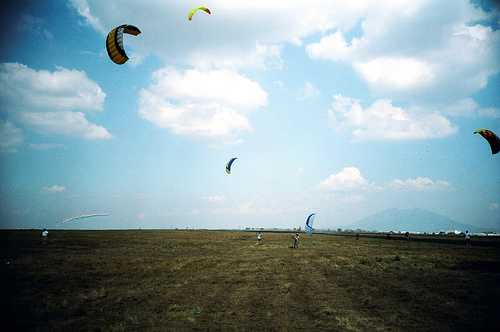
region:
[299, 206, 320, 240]
kite flying in the sky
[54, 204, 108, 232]
kite flying in the sky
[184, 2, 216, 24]
kite flying in the sky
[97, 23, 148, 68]
kite flying in the sky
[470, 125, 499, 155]
kite flying in the sky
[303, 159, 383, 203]
fluffy white cloud in the sky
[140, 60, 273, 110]
fluffy white cloud in the sky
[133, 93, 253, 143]
fluffy white cloud in the sky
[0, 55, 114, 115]
fluffy white cloud in the sky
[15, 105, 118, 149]
fluffy white cloud in the sky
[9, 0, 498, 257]
a bunch of kites flying in the sky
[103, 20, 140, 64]
a yellow, white and blue kite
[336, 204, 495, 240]
a grey colored mountain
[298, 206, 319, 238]
a white and blue kite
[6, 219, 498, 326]
a large open field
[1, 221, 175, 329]
the dark edges of a photograph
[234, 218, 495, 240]
a tree line behind the field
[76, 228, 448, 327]
brown and green grass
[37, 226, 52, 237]
a tiny person wearing a white shirt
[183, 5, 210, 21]
a kite that has yellow, green, and red colors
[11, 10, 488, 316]
People are flying some colorful kites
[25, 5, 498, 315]
People are out in a big field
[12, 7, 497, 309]
People are getting some recreation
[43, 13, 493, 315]
People are having some fun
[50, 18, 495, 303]
People are out in the sunshine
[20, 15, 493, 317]
People are away from the big city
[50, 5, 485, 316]
People are enjoying their time off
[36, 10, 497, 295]
People are enjoying each other's company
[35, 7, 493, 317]
People are testing their kites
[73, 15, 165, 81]
A kite is in the air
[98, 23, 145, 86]
a parachute in the sky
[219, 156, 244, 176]
a blue and yellow parachute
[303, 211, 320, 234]
a blue parachute landing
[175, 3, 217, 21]
a rainbow colored parachute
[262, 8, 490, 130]
clouds in the sky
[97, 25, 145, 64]
white yellow and blue parachute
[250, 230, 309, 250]
people standing in a field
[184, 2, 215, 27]
person parachuting in the clear blue sky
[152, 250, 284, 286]
brown and green grass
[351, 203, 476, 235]
mountains in the distance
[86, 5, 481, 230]
several wind sails in the sky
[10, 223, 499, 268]
several people flying kites in a field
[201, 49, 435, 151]
cloudy blue skies over the field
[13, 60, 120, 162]
fluffy white clouds in the sky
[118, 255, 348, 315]
green grass of the field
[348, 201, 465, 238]
a mountain in the distance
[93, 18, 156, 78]
a yellow white and black wind sail in the sky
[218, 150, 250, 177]
a blue and yellow wind sail in the sky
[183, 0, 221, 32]
a yellow green and red wind sail in the sky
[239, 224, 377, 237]
many trees growing in the distance